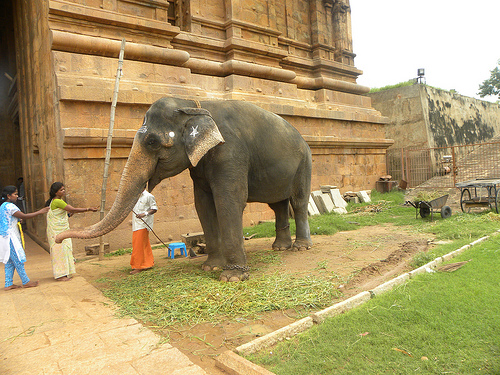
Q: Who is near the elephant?
A: Woman.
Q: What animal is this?
A: An elephant.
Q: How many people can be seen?
A: 3.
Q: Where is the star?
A: On the elephant ear.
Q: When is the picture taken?
A: Daytime.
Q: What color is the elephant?
A: Gray.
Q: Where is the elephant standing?
A: In dirt.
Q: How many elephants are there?
A: 1.